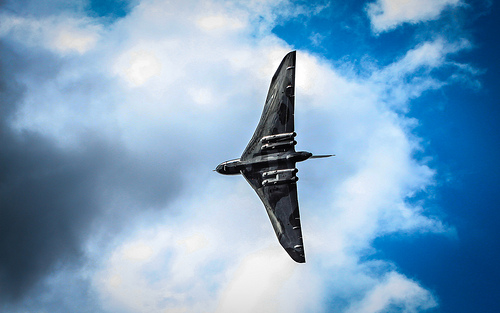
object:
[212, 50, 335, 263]
jet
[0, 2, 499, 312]
sky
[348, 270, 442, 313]
cloud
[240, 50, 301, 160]
wing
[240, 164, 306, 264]
wing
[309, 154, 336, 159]
tail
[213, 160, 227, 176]
nose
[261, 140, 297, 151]
engine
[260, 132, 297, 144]
engine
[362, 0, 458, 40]
cloud